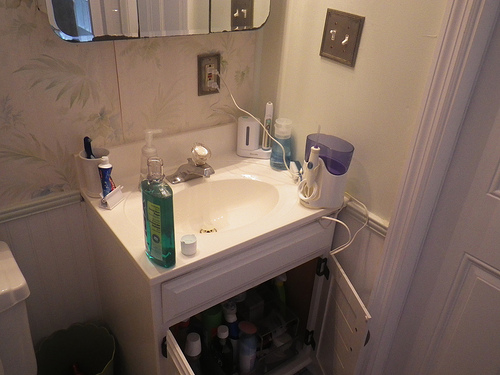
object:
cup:
[79, 149, 110, 200]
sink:
[147, 172, 282, 234]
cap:
[179, 230, 196, 258]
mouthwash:
[139, 155, 176, 267]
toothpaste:
[98, 156, 118, 203]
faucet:
[165, 143, 215, 186]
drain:
[199, 221, 215, 236]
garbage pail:
[37, 321, 121, 374]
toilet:
[1, 239, 37, 375]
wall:
[262, 2, 457, 306]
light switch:
[318, 8, 364, 67]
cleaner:
[271, 277, 296, 329]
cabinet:
[167, 242, 335, 374]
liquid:
[269, 137, 292, 167]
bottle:
[271, 119, 295, 170]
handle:
[302, 146, 324, 188]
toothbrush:
[302, 118, 324, 195]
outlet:
[197, 51, 221, 97]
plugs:
[208, 65, 216, 76]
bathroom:
[2, 1, 499, 375]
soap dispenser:
[140, 125, 162, 179]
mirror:
[46, 0, 270, 43]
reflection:
[230, 0, 255, 28]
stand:
[94, 182, 131, 210]